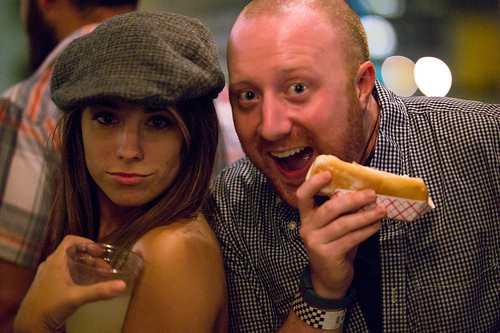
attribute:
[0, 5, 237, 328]
woman — smiling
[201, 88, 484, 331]
dressing shirt — dress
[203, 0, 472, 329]
man — smiling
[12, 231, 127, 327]
hand — woman's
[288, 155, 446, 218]
sandwich — hot dog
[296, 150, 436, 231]
sandwich — hot dog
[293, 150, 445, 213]
sandwich — hot dog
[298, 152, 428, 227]
sandwich — hot dog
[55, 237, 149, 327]
cup — clear, plastic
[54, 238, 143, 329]
cup — plastic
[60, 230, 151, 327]
cup — clear, plastic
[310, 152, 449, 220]
bun — one, white, large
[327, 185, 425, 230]
container — red, white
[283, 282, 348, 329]
bracelet — white, black 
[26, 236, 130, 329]
hand — female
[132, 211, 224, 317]
shoulder — female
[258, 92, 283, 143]
nose — male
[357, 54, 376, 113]
ear — male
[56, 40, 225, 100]
hat — gray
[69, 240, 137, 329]
glass — half-full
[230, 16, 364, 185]
man — smiling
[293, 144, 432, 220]
dog — hot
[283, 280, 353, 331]
bracelet — white, black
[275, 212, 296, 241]
button — shirt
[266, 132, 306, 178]
mouth — open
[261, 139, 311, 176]
teeth — some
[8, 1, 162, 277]
man — one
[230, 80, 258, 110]
eye — male